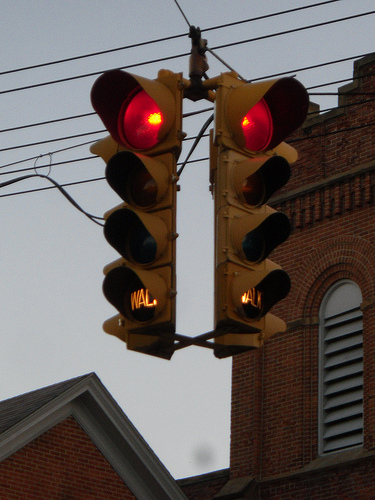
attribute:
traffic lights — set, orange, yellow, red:
[70, 52, 322, 374]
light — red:
[110, 82, 171, 154]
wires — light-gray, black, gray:
[2, 2, 374, 68]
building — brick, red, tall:
[207, 45, 374, 500]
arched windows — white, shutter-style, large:
[305, 265, 374, 470]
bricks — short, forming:
[278, 169, 374, 223]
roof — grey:
[8, 364, 89, 429]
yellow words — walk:
[123, 282, 160, 315]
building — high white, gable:
[6, 366, 180, 500]